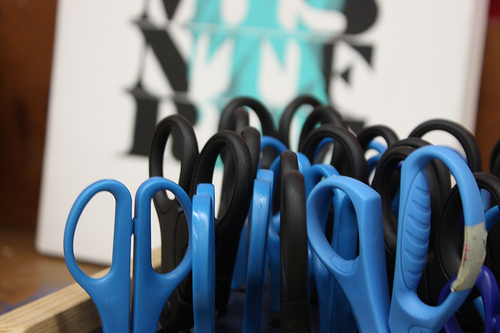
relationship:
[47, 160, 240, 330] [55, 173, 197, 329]
collection of scissors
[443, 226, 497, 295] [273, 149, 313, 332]
tape on scissors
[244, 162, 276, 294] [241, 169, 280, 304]
handle of scissors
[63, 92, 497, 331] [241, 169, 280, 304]
group of scissors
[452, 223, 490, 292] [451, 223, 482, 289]
handle of scissors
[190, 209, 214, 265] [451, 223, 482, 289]
part of scissors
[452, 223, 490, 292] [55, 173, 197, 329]
handle of scissors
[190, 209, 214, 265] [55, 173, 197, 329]
part of scissors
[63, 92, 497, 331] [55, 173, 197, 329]
group of scissors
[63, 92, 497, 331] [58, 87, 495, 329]
group of scissors.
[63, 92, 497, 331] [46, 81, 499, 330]
group of scissors..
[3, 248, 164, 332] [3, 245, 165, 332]
container made wood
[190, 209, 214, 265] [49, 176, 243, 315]
part of scissors